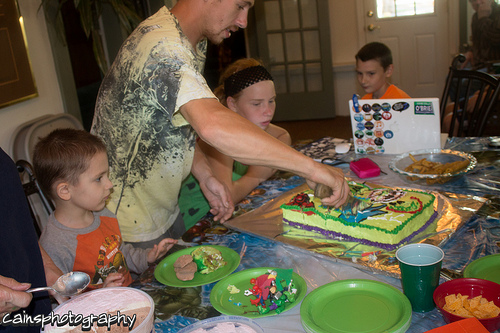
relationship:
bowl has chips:
[434, 277, 499, 328] [452, 295, 489, 313]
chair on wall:
[15, 113, 85, 176] [2, 0, 88, 169]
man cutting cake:
[89, 0, 347, 248] [283, 179, 439, 248]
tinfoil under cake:
[220, 171, 493, 276] [283, 179, 439, 248]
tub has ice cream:
[40, 285, 167, 332] [86, 294, 131, 309]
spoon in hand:
[32, 269, 93, 298] [1, 275, 30, 325]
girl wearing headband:
[209, 58, 298, 206] [223, 63, 280, 95]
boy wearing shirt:
[349, 41, 414, 147] [352, 87, 417, 151]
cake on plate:
[192, 246, 224, 274] [153, 242, 240, 284]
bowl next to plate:
[434, 277, 499, 328] [463, 251, 498, 282]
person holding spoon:
[0, 137, 47, 331] [32, 269, 93, 298]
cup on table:
[392, 244, 446, 316] [75, 135, 494, 332]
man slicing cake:
[89, 0, 347, 248] [283, 179, 439, 248]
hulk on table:
[157, 287, 214, 323] [75, 135, 494, 332]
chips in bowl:
[452, 295, 489, 313] [434, 277, 499, 328]